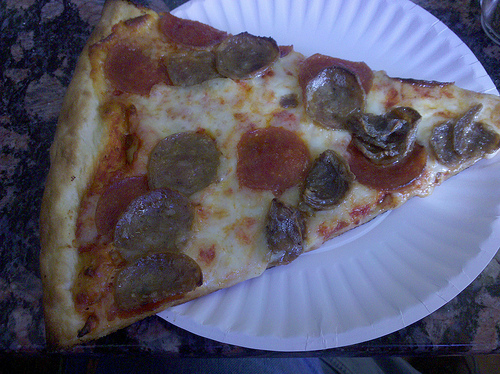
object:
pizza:
[22, 0, 500, 349]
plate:
[95, 3, 498, 361]